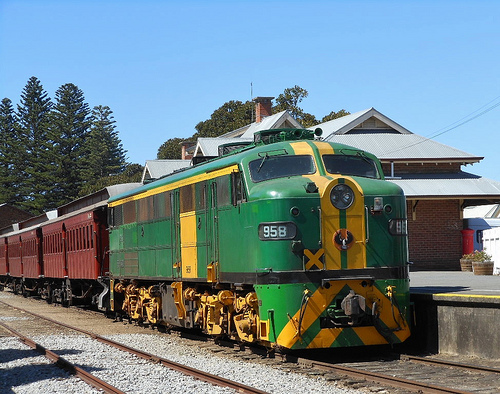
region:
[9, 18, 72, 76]
white clouds in blue sky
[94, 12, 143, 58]
white clouds in blue sky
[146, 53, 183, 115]
white clouds in blue sky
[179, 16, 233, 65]
white clouds in blue sky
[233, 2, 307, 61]
white clouds in blue sky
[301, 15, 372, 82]
white clouds in blue sky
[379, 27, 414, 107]
white clouds in blue sky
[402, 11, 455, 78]
white clouds in blue sky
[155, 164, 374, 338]
green and yellow train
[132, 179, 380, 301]
yellow and green train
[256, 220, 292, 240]
numbers on the front of a train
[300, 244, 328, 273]
a yellow x on the trian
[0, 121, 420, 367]
a green,yellow,and red train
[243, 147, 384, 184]
the front windows of the train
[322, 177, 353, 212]
the light of a train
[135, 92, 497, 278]
a train station beside the train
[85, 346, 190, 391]
a bunch of gravel in between the tracks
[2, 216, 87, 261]
a line of many windows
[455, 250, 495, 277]
a set of flower pots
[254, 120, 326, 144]
the horns of a train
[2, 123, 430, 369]
long red, green and yellow train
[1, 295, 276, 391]
metal train tracks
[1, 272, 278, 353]
wheels on train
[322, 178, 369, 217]
headlight on front of train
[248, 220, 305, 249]
number on front of train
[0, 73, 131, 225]
tall green evergreen trees in back of train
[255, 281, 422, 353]
triangular shaped stripes on front of train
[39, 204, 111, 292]
red car behind green and yellow train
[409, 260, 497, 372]
concrete platform next to train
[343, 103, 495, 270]
brick building next to train platform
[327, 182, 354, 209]
a train engines headlight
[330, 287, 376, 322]
a train car coupler attachment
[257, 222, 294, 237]
the trains identification number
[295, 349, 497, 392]
the steel railroad tracks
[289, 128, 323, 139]
the trains air horns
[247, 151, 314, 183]
the train engines windshield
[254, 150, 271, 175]
the trains windshield wiper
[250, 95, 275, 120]
a red brick chimney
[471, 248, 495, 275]
a potted flower plant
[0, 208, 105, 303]
brown passenger train cars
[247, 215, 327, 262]
This says 958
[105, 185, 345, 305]
This is a picture of a train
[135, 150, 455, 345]
The train is green and yellow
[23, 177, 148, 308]
These are train cars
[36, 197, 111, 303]
The train cars are red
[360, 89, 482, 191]
This is a roof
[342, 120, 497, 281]
This is a picture of a building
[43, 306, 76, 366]
This is a train track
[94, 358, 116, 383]
These are small stones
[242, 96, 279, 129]
This is a chimney